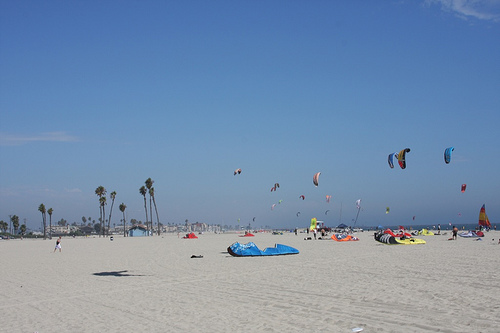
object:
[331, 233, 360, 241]
structure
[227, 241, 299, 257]
structure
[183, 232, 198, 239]
structure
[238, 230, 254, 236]
structure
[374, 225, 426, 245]
structure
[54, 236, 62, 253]
people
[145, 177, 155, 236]
palm tree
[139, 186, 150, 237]
palm tree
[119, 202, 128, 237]
palm tree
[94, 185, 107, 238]
palm tree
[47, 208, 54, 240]
palm tree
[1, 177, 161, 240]
grove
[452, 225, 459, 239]
people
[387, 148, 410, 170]
flags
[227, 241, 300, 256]
kite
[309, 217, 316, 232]
lifeguard stand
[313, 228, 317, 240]
person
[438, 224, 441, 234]
person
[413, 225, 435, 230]
water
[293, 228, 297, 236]
people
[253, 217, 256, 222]
kites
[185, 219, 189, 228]
trees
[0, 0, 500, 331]
sunshine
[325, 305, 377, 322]
track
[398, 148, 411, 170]
kite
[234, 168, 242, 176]
kite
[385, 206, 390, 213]
kite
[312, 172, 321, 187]
kite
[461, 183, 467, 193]
kite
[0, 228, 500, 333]
sand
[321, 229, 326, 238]
person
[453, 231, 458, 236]
shorts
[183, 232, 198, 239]
kite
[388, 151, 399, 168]
kite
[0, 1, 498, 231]
sky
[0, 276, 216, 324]
tracks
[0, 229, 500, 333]
beach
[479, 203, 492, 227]
sailboat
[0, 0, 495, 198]
air